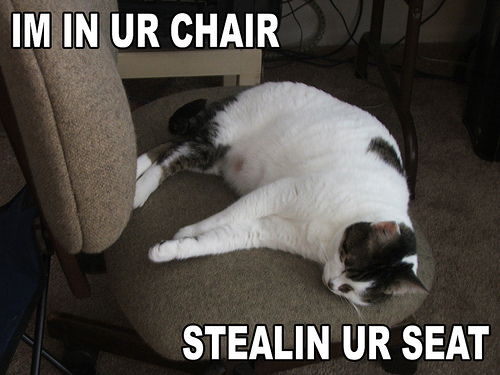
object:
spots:
[146, 95, 239, 185]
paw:
[151, 239, 165, 248]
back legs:
[136, 102, 244, 191]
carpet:
[5, 47, 500, 375]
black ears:
[384, 266, 430, 295]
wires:
[279, 0, 443, 200]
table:
[141, 0, 500, 116]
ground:
[338, 160, 382, 201]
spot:
[364, 136, 408, 179]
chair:
[0, 0, 436, 375]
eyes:
[343, 257, 355, 270]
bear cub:
[132, 81, 431, 324]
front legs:
[173, 176, 304, 261]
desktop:
[457, 0, 500, 161]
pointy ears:
[366, 220, 401, 254]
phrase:
[179, 322, 492, 363]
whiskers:
[350, 301, 370, 325]